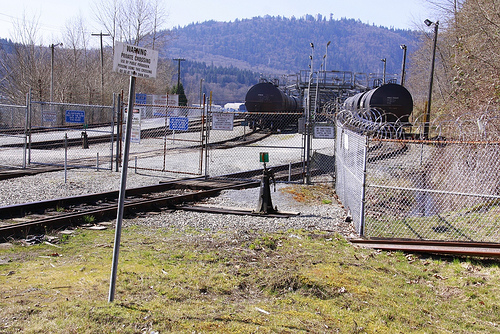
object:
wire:
[0, 12, 90, 37]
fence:
[331, 107, 499, 243]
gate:
[28, 88, 206, 175]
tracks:
[0, 120, 126, 135]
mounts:
[0, 11, 448, 97]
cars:
[340, 83, 413, 137]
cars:
[244, 82, 302, 135]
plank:
[170, 201, 302, 217]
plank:
[347, 237, 500, 257]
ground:
[1, 120, 348, 230]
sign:
[112, 40, 160, 82]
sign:
[64, 110, 84, 123]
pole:
[106, 75, 137, 302]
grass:
[0, 219, 499, 333]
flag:
[258, 151, 270, 162]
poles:
[99, 29, 106, 105]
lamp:
[423, 18, 438, 30]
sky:
[0, 1, 463, 59]